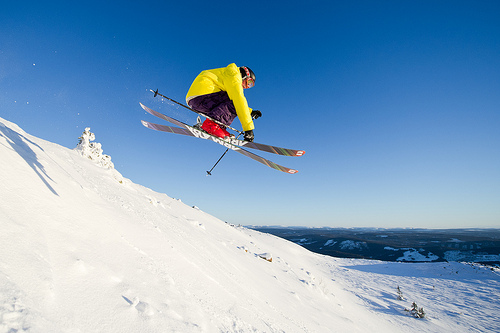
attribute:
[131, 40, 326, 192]
skier — bright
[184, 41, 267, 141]
jacket — yellow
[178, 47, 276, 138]
jacket — bright, yellow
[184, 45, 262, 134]
jacket — yellow, bright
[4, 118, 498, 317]
snow — white 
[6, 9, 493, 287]
sky — clear , blue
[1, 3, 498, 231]
sky — clear , blue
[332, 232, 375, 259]
hill — snowy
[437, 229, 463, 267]
hill — snowy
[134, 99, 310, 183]
skis — crossed, decorative design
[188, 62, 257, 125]
jacket — yellow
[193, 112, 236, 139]
boots — red, ski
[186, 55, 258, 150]
skier — one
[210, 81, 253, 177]
poles — ski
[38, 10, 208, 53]
sky — blue, clear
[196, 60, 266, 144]
skier — one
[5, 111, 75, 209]
shadow — one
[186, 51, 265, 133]
person — one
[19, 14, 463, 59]
sky — blue, clear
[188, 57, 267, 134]
person — one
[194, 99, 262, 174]
poles — ski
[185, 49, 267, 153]
person — one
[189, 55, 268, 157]
person — one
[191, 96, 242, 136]
pants — purple, ski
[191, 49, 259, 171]
skier — airborne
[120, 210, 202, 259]
snow — white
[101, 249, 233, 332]
snow — white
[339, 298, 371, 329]
snow — white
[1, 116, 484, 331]
snow — white 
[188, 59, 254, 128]
jacket — yellow 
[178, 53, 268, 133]
jacket — yellow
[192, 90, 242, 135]
pants — purple 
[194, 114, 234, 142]
shoes — red 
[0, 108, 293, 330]
hill — side 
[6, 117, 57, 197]
shadow —  man skiing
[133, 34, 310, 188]
man — mid-air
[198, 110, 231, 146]
shoes — red 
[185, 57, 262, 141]
jacket — Man's yellow ski 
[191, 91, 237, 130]
pants — Men's purple ski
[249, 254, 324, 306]
snow — Barren 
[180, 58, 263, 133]
jacket — yellow 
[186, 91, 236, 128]
pants — purple 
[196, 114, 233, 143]
boots — red 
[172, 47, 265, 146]
man — air 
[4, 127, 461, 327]
snow — ground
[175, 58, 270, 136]
jacket — yellow 